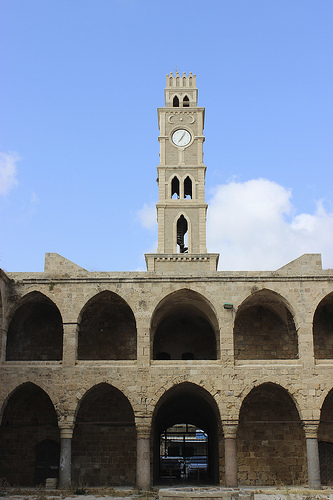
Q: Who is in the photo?
A: No visible person.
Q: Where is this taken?
A: Outside in the sun.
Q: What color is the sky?
A: Blue.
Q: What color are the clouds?
A: White.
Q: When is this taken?
A: During the day.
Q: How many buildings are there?
A: One.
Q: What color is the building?
A: Beige.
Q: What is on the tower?
A: A clock.